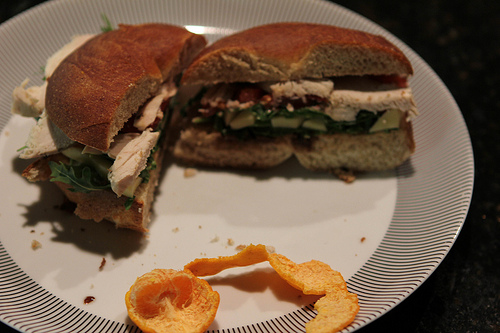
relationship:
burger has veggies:
[171, 19, 418, 173] [214, 105, 378, 141]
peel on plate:
[189, 234, 364, 332] [5, 0, 477, 330]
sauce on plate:
[80, 287, 103, 313] [5, 0, 477, 330]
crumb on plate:
[182, 164, 205, 180] [5, 0, 477, 330]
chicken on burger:
[269, 78, 412, 112] [171, 19, 418, 173]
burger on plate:
[171, 19, 418, 173] [5, 0, 477, 330]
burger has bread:
[171, 19, 418, 173] [181, 20, 419, 85]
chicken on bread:
[269, 78, 412, 112] [181, 20, 419, 85]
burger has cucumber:
[171, 19, 418, 173] [223, 100, 261, 130]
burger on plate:
[24, 20, 204, 241] [5, 0, 477, 330]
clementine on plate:
[120, 267, 220, 328] [5, 0, 477, 330]